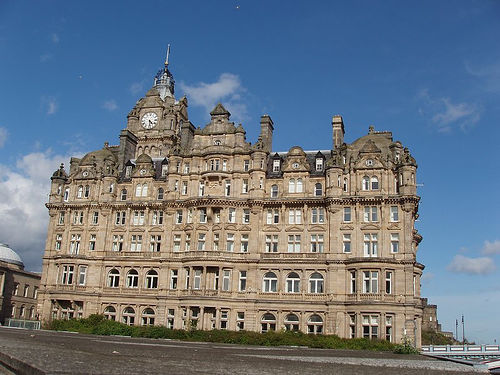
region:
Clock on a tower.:
[128, 106, 168, 130]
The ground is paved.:
[32, 328, 166, 371]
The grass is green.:
[93, 317, 178, 334]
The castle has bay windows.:
[342, 260, 398, 295]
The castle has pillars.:
[179, 305, 223, 330]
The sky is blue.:
[434, 204, 472, 249]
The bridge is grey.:
[426, 340, 498, 369]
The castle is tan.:
[38, 109, 434, 357]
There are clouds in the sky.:
[458, 270, 491, 338]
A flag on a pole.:
[156, 34, 187, 76]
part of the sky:
[299, 12, 370, 79]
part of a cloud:
[465, 254, 485, 273]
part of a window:
[301, 228, 322, 249]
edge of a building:
[401, 250, 421, 317]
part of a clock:
[141, 105, 162, 122]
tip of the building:
[252, 122, 274, 132]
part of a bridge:
[465, 335, 490, 362]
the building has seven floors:
[35, 38, 422, 350]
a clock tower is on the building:
[110, 41, 195, 237]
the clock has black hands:
[138, 108, 158, 128]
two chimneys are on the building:
[255, 110, 347, 185]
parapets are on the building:
[40, 186, 422, 213]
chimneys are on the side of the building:
[115, 111, 195, 182]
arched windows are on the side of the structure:
[100, 261, 327, 336]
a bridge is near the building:
[420, 330, 497, 370]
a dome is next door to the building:
[0, 236, 111, 327]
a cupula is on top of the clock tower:
[151, 38, 176, 82]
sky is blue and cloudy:
[79, 24, 430, 121]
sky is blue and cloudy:
[11, 43, 41, 252]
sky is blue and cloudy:
[408, 62, 488, 346]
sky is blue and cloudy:
[3, 46, 80, 309]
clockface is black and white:
[130, 102, 178, 132]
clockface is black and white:
[134, 99, 159, 135]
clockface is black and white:
[135, 91, 172, 161]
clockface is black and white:
[108, 80, 172, 158]